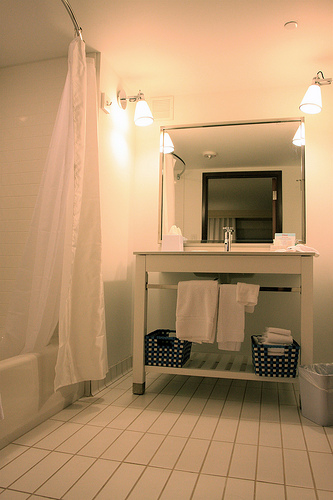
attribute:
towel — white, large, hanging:
[174, 279, 219, 348]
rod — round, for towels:
[145, 281, 304, 295]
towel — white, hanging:
[215, 285, 246, 350]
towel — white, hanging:
[235, 281, 260, 315]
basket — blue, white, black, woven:
[250, 334, 302, 380]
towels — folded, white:
[260, 325, 293, 359]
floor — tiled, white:
[1, 364, 331, 500]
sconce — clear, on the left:
[133, 100, 154, 130]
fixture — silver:
[116, 88, 146, 112]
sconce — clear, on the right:
[298, 83, 324, 117]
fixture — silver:
[312, 71, 332, 88]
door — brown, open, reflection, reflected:
[200, 169, 284, 245]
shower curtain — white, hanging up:
[25, 38, 109, 392]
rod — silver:
[58, 2, 85, 41]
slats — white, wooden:
[186, 353, 253, 378]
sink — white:
[131, 247, 319, 262]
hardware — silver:
[221, 224, 236, 252]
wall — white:
[92, 53, 151, 395]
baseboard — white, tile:
[84, 354, 133, 396]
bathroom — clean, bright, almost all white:
[2, 0, 330, 499]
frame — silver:
[157, 116, 307, 246]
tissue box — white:
[160, 234, 185, 253]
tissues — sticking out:
[166, 226, 183, 236]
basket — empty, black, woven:
[143, 328, 191, 369]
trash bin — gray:
[297, 362, 331, 426]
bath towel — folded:
[261, 333, 295, 345]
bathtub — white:
[1, 342, 81, 441]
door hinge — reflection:
[269, 188, 279, 202]